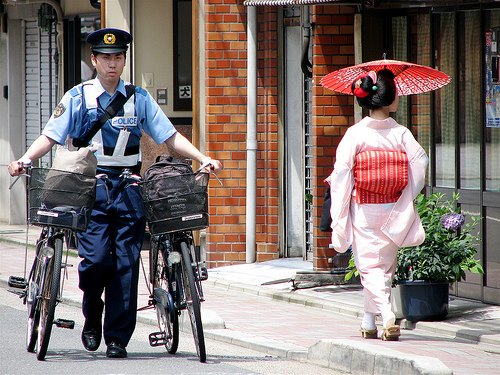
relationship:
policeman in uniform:
[13, 24, 225, 179] [11, 75, 227, 305]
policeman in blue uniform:
[13, 24, 225, 179] [31, 78, 186, 154]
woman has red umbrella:
[307, 77, 446, 346] [317, 52, 451, 106]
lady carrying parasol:
[307, 77, 446, 346] [317, 52, 451, 106]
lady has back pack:
[307, 77, 446, 346] [353, 144, 411, 207]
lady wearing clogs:
[307, 77, 446, 346] [356, 316, 407, 342]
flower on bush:
[438, 208, 470, 239] [420, 192, 488, 288]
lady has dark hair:
[307, 77, 446, 346] [349, 70, 399, 109]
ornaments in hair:
[368, 85, 383, 94] [349, 70, 399, 109]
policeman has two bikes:
[13, 24, 225, 179] [9, 149, 227, 370]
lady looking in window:
[307, 77, 446, 346] [446, 19, 495, 206]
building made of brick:
[224, 10, 318, 326] [213, 24, 241, 66]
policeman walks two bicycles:
[13, 24, 225, 179] [9, 149, 227, 370]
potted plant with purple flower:
[420, 192, 488, 288] [438, 208, 470, 239]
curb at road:
[313, 342, 405, 374] [90, 292, 187, 374]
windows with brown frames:
[462, 13, 477, 186] [450, 7, 487, 191]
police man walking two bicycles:
[13, 24, 225, 179] [9, 149, 227, 370]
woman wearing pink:
[307, 77, 446, 346] [372, 132, 388, 145]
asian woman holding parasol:
[307, 77, 446, 346] [317, 52, 451, 106]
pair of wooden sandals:
[354, 316, 405, 341] [356, 316, 407, 342]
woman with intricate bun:
[307, 77, 446, 346] [350, 71, 375, 96]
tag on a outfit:
[114, 115, 141, 128] [31, 78, 186, 154]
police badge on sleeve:
[53, 103, 68, 119] [39, 95, 76, 150]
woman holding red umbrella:
[307, 77, 446, 346] [317, 52, 451, 106]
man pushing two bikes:
[13, 24, 225, 179] [9, 149, 227, 370]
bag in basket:
[53, 140, 99, 172] [26, 169, 100, 232]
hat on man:
[86, 24, 135, 56] [26, 19, 181, 147]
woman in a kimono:
[307, 77, 446, 346] [325, 118, 432, 302]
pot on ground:
[403, 266, 457, 325] [441, 324, 490, 362]